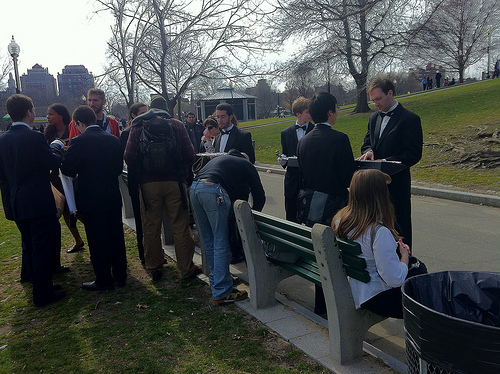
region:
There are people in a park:
[23, 47, 463, 322]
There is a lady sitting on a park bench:
[170, 130, 460, 345]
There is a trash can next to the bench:
[200, 175, 490, 347]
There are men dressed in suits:
[20, 65, 440, 332]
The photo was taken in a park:
[25, 27, 475, 337]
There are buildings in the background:
[15, 0, 450, 265]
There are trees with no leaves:
[87, 5, 467, 140]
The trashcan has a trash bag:
[351, 235, 491, 370]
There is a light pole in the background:
[5, 20, 115, 170]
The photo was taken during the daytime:
[13, 19, 426, 358]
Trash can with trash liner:
[406, 271, 498, 348]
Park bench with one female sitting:
[236, 201, 383, 320]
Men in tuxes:
[203, 63, 435, 155]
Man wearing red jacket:
[66, 85, 125, 138]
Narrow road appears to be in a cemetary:
[243, 121, 471, 321]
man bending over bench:
[199, 142, 265, 243]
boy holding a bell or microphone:
[261, 144, 292, 171]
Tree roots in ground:
[434, 118, 495, 179]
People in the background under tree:
[410, 60, 470, 93]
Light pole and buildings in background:
[5, 37, 92, 93]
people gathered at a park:
[25, 67, 415, 342]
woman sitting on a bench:
[333, 166, 425, 328]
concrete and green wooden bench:
[240, 202, 401, 341]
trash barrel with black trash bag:
[395, 254, 499, 371]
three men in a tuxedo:
[202, 77, 430, 238]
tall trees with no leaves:
[125, 0, 388, 123]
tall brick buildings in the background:
[18, 21, 113, 116]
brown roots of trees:
[427, 107, 497, 183]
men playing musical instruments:
[287, 63, 419, 213]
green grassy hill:
[438, 80, 485, 127]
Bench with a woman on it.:
[190, 167, 489, 332]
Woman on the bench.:
[283, 198, 442, 313]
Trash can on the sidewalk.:
[363, 217, 498, 332]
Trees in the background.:
[106, 17, 360, 142]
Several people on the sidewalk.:
[17, 82, 355, 322]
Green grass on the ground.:
[102, 239, 282, 369]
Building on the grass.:
[172, 53, 314, 140]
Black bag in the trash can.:
[388, 255, 490, 368]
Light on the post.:
[1, 36, 71, 123]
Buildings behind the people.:
[16, 47, 140, 150]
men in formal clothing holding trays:
[181, 55, 447, 262]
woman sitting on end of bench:
[272, 150, 424, 320]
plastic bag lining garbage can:
[391, 251, 491, 366]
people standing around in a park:
[10, 60, 247, 300]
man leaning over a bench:
[180, 140, 265, 310]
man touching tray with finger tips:
[347, 66, 427, 182]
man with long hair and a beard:
[210, 95, 240, 136]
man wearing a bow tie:
[361, 70, 401, 132]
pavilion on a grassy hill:
[170, 62, 280, 129]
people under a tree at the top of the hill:
[411, 40, 493, 112]